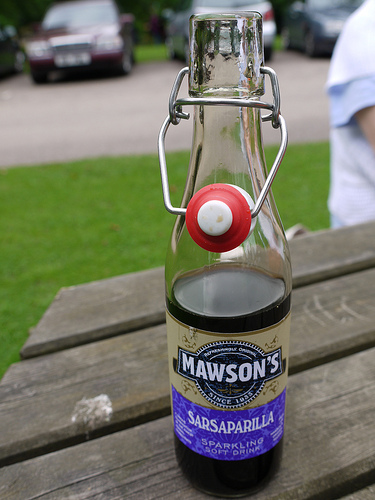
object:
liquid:
[165, 265, 291, 496]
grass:
[2, 167, 102, 269]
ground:
[5, 59, 373, 371]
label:
[173, 340, 286, 409]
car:
[162, 1, 277, 66]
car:
[283, 0, 366, 57]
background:
[0, 0, 374, 164]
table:
[0, 220, 375, 500]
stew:
[27, 1, 140, 84]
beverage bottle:
[157, 10, 292, 498]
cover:
[185, 183, 251, 253]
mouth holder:
[188, 11, 265, 98]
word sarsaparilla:
[188, 411, 274, 434]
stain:
[71, 393, 113, 439]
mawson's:
[183, 353, 279, 383]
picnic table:
[1, 218, 375, 500]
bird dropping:
[72, 393, 114, 440]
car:
[25, 0, 134, 83]